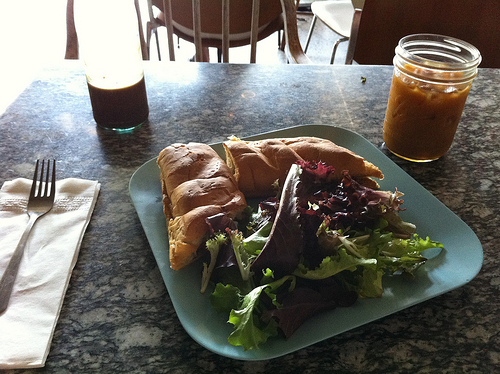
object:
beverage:
[382, 60, 473, 162]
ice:
[444, 86, 459, 93]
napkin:
[0, 176, 102, 371]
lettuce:
[198, 158, 443, 359]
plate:
[129, 124, 486, 361]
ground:
[0, 0, 355, 84]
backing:
[63, 0, 302, 63]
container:
[381, 33, 483, 164]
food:
[155, 134, 446, 353]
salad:
[197, 160, 445, 353]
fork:
[0, 159, 57, 316]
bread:
[155, 134, 384, 271]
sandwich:
[156, 135, 386, 271]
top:
[0, 63, 499, 373]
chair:
[62, 0, 362, 63]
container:
[74, 0, 150, 135]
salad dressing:
[86, 69, 150, 133]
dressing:
[380, 61, 473, 164]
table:
[1, 63, 500, 373]